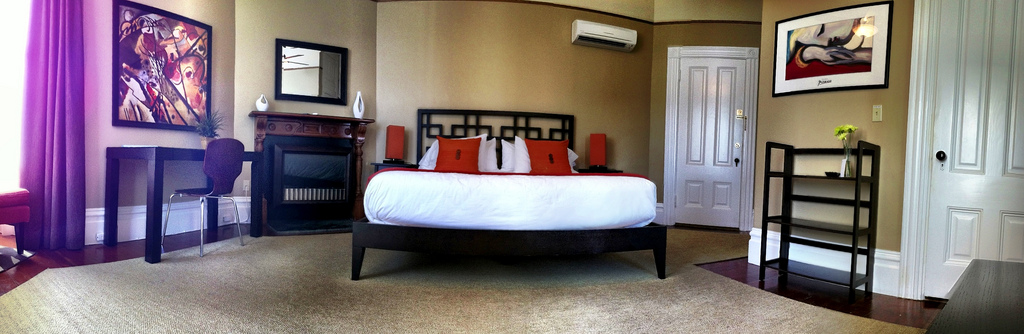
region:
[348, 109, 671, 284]
a bed with a black frame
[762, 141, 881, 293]
a black bookshelf against the wall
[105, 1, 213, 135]
a black framed painting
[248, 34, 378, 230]
a mirror hanging over a fireplace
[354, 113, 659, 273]
red and white pillow sitting on top of a bed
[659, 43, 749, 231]
a white door with a black handle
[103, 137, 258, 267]
a chair sitting in front of a black desk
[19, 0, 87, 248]
red drapes hanging on the window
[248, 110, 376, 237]
a black fireplace with a wooden frame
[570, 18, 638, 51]
a white elongated vent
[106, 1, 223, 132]
ART HANGING ON THE WALL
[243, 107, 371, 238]
BLACK INDOOR FIREPLACE NOT LIT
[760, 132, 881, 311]
BLACK SHELVES WITH YELLOW FLOWER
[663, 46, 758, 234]
WHITE ENTRANCE DOOR CLOSED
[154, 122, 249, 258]
MODERN CHAIR TUCKED UNDER DESK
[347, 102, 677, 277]
MODERN STYLE BED WITH RED PILLOWS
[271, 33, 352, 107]
MIRROR ABOVE FIREPLACE MANTLE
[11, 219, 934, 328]
TAN CARPET IN BEDROOM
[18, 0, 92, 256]
BURGANDY CURTAIN SEMI OPENED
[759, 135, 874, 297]
The black shelf against the wall.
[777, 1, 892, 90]
The frame above the black shelf.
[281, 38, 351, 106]
The framed mirror above the fireplace.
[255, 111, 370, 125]
The mantle of the fire place.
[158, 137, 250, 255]
The chair in front of the table against the wall.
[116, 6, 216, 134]
The frame above the table against the wall.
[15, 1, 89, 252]
The curtains hanging near the window.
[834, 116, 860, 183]
The flowers in a vase on the black shelf.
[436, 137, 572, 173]
The red pillows on the bed.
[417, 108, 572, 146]
The black headboard of the bed.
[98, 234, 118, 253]
leg of the furniture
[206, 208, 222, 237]
leg of the furniture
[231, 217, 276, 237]
leg of the furniture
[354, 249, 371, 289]
leg of the furniture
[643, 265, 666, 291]
leg of the furniture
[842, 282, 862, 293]
leg of the furniture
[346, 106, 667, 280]
bed is against the wall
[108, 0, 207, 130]
art work is above desk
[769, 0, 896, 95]
art work is attached to the wall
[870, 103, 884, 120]
outlet is attached to wall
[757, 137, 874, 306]
shelf is under art work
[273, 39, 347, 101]
black mirror is up against the wall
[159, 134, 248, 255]
chair is tucked under desk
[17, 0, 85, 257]
window curtain is purple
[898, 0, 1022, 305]
door is white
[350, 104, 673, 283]
large wide wooden bed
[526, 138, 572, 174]
large square red pillow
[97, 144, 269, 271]
large wide dark desk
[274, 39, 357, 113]
large square reflective mirror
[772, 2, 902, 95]
large wide white picture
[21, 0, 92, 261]
tall long purple drape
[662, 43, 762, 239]
large tall white door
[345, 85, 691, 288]
a large black bed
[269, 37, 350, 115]
a black wall mirror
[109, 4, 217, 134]
a large black picture frame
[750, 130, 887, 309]
a tall black rack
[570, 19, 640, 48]
a long white ac unit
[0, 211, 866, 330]
a large area rug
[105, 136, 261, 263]
a long black table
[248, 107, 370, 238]
a brown and black fireplace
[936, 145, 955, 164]
a dark doorknob